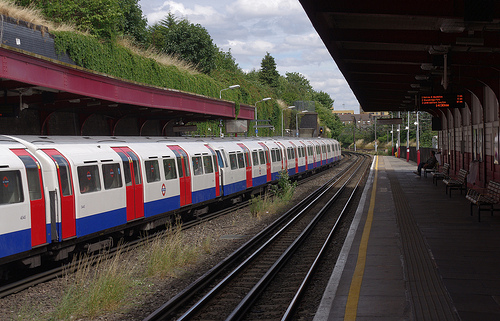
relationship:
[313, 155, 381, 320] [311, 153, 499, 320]
lines on platform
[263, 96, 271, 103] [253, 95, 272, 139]
light attached to pole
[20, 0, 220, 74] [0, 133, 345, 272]
trees behind train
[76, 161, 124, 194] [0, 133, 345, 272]
windows on train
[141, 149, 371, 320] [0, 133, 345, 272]
tracks next to train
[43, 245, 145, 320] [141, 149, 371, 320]
grass next to tracks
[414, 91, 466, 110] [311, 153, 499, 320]
sign above platform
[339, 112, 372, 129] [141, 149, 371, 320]
building behind tracks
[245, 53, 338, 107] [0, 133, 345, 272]
trees behind train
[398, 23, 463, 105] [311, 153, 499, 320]
lights above platform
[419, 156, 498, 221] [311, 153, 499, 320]
benches along platform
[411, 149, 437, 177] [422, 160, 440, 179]
person sitting on bench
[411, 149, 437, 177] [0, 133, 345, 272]
person watching train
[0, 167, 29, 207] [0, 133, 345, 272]
window on train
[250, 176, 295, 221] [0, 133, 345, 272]
grass growing beside train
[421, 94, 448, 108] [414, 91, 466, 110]
lettering on sign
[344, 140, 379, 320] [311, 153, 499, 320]
line on platform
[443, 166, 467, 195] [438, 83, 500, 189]
bench against wall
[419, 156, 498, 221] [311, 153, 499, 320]
benches on platform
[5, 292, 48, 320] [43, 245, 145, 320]
stones beside grass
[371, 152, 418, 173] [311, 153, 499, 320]
sunlight on platform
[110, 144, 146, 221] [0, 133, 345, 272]
door on train